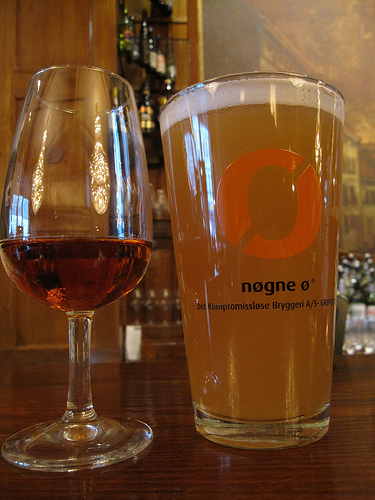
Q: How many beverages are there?
A: 2.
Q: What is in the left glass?
A: Wine.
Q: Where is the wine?
A: In the wineglass.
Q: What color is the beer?
A: Yellow.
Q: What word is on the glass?
A: Nogne o.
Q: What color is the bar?
A: Brown.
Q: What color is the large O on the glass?
A: Orange.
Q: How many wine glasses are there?
A: 1.